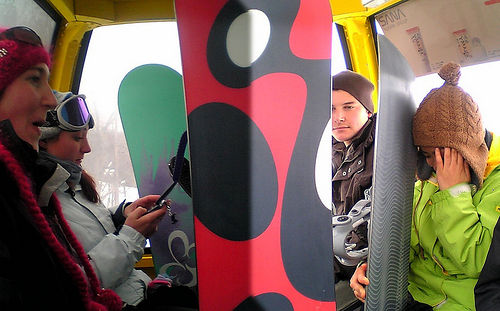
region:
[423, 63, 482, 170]
person in beige knitted cap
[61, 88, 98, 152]
woman in gray goggles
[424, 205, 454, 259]
woman in lime green jacket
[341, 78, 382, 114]
man in brown knitted cap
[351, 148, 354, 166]
man wearing brown jacket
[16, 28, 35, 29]
woman with red and black cap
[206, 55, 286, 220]
red black and white snowboard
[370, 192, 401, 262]
woman with gray snowboard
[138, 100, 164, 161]
teal and purple snowboard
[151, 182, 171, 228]
woman holding cell phone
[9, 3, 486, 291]
A group of snowboarders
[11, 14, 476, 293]
There are three women and one man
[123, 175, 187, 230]
Girl is on her cell phone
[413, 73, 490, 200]
Girl with her hand on her face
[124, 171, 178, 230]
Her phone is a flip phone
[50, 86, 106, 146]
She has ski goggles on her head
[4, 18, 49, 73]
She has sunglasses over her beanie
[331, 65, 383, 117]
He is wearing a brown beanie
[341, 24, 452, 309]
Her right hand is on the snowboard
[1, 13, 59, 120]
The woman has on a hat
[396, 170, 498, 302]
The woman has on a green jacket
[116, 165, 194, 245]
The woman has a device in her hand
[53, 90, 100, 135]
The woman is wearing snow goggles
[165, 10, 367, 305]
The snow board in the color red and black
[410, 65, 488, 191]
The woman has on a brown hat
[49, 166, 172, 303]
The woman has on a white jacket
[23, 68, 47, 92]
The eye of the woman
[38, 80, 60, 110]
The nose of the woman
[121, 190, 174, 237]
The hands of the woman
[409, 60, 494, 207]
a person hiding their face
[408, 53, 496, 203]
a person wearing a brown beany hiding their face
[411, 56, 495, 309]
a person wearing a lime green jacket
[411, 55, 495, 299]
a person wearing a brown beany and green jacket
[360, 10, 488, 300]
a woman holding a snow board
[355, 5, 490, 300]
a woman holding a silver snow board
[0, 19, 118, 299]
2 women sitting together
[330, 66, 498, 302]
a young man sitting next to a young lady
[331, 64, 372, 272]
a young man wearing a black jacket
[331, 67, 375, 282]
a young man wearing a black beany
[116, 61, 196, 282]
Green and purple snowboard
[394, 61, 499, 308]
Person covering their face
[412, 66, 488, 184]
Brown knitted ski cap with flaps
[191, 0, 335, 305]
Red, white and navy blue swirl snowboard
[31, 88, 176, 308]
Female snowboarder texting on a phone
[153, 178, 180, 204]
A slim cellular phone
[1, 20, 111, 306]
A woman in a red sweater and ski cap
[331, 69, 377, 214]
A man looking at a snowboard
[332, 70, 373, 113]
A black knit cap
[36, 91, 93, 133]
A pair of snow goggles